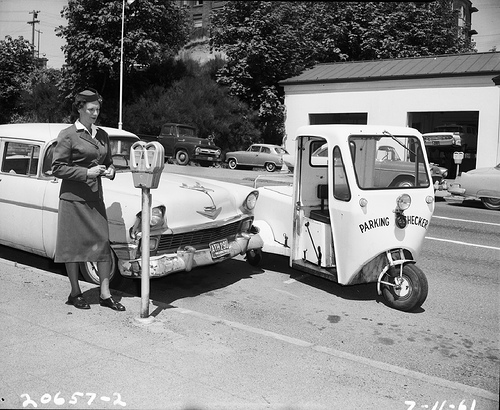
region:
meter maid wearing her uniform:
[42, 79, 129, 324]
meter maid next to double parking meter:
[38, 78, 178, 333]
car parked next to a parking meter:
[5, 106, 264, 301]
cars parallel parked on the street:
[144, 111, 303, 182]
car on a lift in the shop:
[396, 103, 486, 197]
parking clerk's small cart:
[232, 113, 451, 318]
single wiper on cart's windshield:
[344, 123, 436, 203]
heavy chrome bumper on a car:
[120, 224, 272, 279]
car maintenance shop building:
[260, 42, 499, 198]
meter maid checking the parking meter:
[36, 74, 175, 329]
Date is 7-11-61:
[393, 391, 468, 408]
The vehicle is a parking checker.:
[270, 104, 461, 314]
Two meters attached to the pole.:
[121, 123, 176, 326]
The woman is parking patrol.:
[55, 75, 126, 312]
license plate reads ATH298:
[202, 230, 242, 270]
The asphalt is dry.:
[238, 291, 370, 365]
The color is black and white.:
[10, 7, 474, 394]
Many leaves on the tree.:
[82, 2, 410, 68]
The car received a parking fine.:
[9, 94, 276, 297]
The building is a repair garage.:
[302, 97, 487, 169]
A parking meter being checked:
[127, 135, 168, 310]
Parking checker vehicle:
[305, 120, 440, 312]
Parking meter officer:
[56, 90, 108, 305]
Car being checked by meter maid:
[2, 135, 257, 270]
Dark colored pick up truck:
[160, 120, 210, 165]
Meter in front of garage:
[450, 146, 460, 176]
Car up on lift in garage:
[417, 123, 470, 148]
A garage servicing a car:
[260, 44, 473, 206]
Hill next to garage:
[118, 42, 263, 136]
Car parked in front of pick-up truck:
[233, 138, 291, 174]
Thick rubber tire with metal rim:
[384, 263, 426, 309]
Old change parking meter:
[128, 141, 164, 189]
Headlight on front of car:
[244, 192, 260, 214]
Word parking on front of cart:
[355, 216, 390, 236]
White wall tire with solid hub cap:
[175, 150, 192, 165]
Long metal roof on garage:
[313, 56, 413, 85]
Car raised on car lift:
[419, 121, 476, 149]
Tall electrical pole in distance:
[28, 6, 40, 47]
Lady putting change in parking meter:
[57, 93, 121, 310]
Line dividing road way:
[441, 233, 491, 254]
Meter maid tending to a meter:
[32, 71, 199, 343]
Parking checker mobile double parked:
[250, 110, 475, 325]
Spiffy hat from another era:
[61, 78, 111, 136]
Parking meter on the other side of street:
[431, 120, 478, 208]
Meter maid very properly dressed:
[40, 71, 140, 330]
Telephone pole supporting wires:
[3, 3, 81, 64]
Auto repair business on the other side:
[247, 33, 499, 193]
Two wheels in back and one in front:
[242, 108, 441, 330]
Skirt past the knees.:
[51, 187, 132, 272]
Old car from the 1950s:
[122, 176, 279, 296]